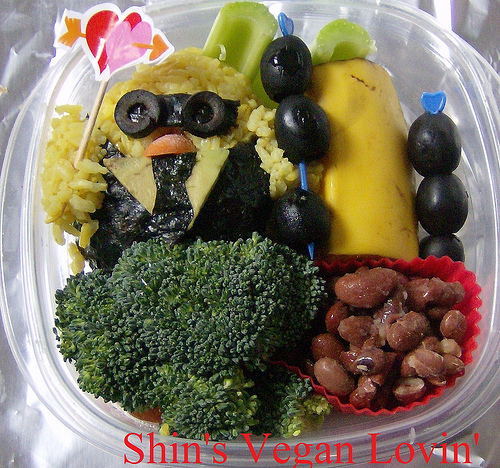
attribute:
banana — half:
[307, 57, 414, 265]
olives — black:
[405, 114, 470, 261]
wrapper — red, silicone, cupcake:
[307, 247, 493, 429]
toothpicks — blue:
[276, 4, 318, 258]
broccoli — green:
[49, 248, 344, 415]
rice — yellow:
[38, 45, 324, 269]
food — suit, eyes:
[42, 10, 481, 395]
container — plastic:
[29, 53, 134, 443]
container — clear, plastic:
[0, 2, 494, 461]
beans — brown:
[307, 261, 471, 409]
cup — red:
[255, 255, 482, 415]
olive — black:
[407, 107, 469, 179]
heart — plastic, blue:
[419, 90, 452, 117]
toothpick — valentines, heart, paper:
[50, 2, 180, 172]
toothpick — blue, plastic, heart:
[274, 14, 316, 270]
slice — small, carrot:
[140, 135, 202, 157]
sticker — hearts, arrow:
[55, 0, 182, 74]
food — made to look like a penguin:
[39, 2, 481, 442]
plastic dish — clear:
[3, 3, 497, 465]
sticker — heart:
[51, 0, 176, 81]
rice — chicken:
[33, 47, 299, 264]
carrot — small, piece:
[144, 129, 197, 160]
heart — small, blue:
[417, 86, 450, 113]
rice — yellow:
[43, 104, 103, 254]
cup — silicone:
[299, 242, 485, 423]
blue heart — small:
[420, 90, 445, 114]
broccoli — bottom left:
[66, 231, 313, 448]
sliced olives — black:
[119, 93, 224, 135]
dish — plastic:
[1, 2, 483, 456]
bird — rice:
[19, 45, 322, 267]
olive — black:
[415, 172, 469, 237]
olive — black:
[420, 235, 465, 262]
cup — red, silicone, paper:
[284, 251, 484, 414]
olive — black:
[408, 111, 461, 178]